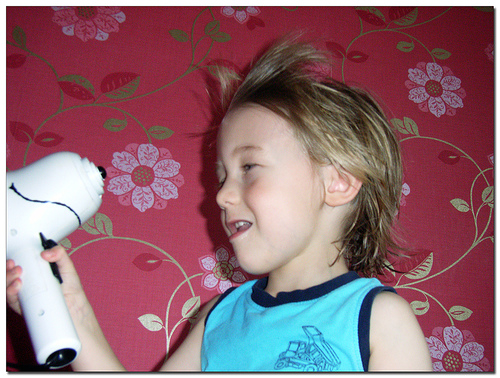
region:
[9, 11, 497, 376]
the pink background with flowers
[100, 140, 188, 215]
the pink and multi color flower on the wall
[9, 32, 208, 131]
the leaves on the wall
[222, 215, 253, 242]
the boy's mouth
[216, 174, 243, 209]
the boy's nose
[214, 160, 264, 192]
the boy's two eyes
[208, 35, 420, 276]
the hair on the boys head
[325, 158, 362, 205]
the boy's left ear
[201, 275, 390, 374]
the light blue sleeveless shirt on the little boy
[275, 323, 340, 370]
the design on the boy's shirt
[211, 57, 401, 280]
the child has light brown hair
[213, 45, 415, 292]
the child's hair is wet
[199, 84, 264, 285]
the child is casting a shadow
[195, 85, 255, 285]
the shadow is on the cloth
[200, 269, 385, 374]
the child is wearing a tank top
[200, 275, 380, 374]
the tank top is blue in color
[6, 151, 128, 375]
the child is holding a hair dryer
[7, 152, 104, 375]
the hair dryer is made of plastic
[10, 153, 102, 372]
the hair dryer is white in color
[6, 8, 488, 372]
the cloth is behind the child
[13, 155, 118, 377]
the blower is plastic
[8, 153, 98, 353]
the blower is white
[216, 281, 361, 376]
the top is blue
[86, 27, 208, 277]
the surface is red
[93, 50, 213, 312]
the surface has flowers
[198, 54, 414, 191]
her hair is standing cause of blowing air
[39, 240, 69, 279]
the power button is black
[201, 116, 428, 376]
the child has her mouth open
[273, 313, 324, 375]
a drawing is on her shirt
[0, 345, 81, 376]
the cable cord is black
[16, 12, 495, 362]
A children holding the hair dryer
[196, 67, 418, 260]
Grey color hair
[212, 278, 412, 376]
Children wearing round neck t-shirt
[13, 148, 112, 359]
White and black color of the hair dryer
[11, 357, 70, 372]
Black color wire of the hair dryer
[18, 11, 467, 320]
Flower designs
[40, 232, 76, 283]
Black color power button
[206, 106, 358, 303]
Face of the children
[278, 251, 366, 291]
Neck of the children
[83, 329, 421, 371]
Hands of the children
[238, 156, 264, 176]
the child's left eye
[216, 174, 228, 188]
the child's right eye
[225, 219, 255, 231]
the child's top row of teeth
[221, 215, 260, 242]
the child's open mouth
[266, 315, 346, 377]
a truck on the child's shirt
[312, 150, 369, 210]
the child's left ear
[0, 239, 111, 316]
the child's right hand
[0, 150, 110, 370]
a blow dryer in the child's hand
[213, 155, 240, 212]
a nose on the child's face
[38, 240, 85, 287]
the thumb on the child's hand